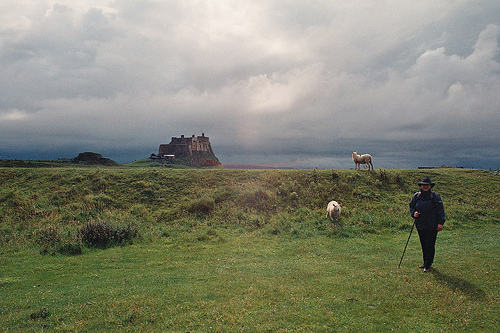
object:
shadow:
[430, 264, 489, 303]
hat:
[417, 177, 435, 188]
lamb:
[351, 151, 373, 170]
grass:
[260, 221, 307, 238]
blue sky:
[0, 0, 498, 169]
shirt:
[409, 190, 444, 221]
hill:
[70, 152, 119, 166]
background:
[0, 0, 499, 229]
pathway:
[0, 168, 349, 171]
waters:
[392, 126, 476, 163]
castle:
[158, 133, 221, 166]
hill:
[121, 159, 223, 169]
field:
[0, 221, 500, 331]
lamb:
[326, 201, 341, 220]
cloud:
[0, 0, 499, 153]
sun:
[206, 0, 289, 104]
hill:
[0, 166, 500, 243]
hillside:
[3, 165, 492, 329]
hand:
[414, 211, 419, 217]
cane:
[398, 220, 416, 268]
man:
[409, 178, 445, 273]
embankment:
[0, 143, 499, 186]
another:
[74, 152, 119, 165]